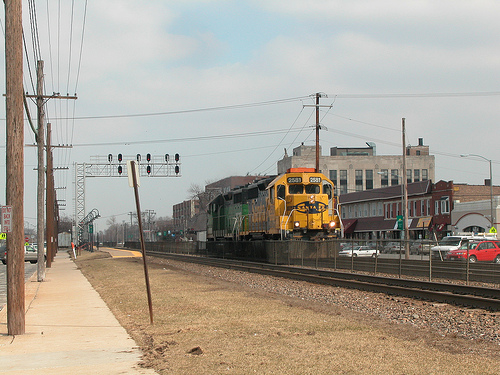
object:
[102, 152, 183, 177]
signal structure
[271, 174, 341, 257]
front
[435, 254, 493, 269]
parking spot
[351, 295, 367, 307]
gravel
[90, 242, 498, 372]
ground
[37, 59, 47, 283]
power lines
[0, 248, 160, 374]
cement sidewalk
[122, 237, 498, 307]
tracks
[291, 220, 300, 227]
front headlight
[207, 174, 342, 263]
train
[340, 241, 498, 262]
lot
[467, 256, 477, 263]
front wheel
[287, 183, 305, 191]
front windows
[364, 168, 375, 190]
windows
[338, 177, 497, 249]
building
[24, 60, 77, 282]
utility poles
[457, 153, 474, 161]
streetlight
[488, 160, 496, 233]
pole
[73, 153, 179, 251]
structure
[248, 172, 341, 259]
locomotive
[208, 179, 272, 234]
cars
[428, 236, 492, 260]
car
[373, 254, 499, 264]
curb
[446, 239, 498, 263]
car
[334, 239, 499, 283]
fence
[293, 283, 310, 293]
rock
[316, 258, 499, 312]
track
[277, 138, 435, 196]
building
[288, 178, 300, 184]
2531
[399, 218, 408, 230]
sign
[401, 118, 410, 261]
pole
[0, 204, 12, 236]
letters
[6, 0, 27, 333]
pole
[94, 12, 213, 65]
clouds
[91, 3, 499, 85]
sky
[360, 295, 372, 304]
rocks